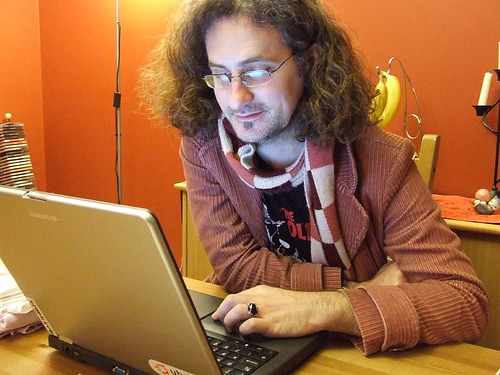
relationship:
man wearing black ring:
[159, 2, 489, 353] [248, 301, 258, 319]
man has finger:
[159, 2, 489, 353] [223, 299, 261, 335]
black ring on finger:
[248, 301, 258, 319] [223, 299, 261, 335]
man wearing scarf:
[159, 2, 489, 353] [197, 109, 385, 254]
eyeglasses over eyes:
[179, 61, 293, 95] [214, 67, 268, 83]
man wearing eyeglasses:
[159, 2, 489, 353] [179, 61, 293, 95]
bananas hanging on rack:
[374, 55, 401, 128] [373, 53, 423, 160]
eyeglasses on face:
[200, 52, 297, 90] [198, 3, 310, 145]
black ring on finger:
[248, 300, 258, 319] [223, 304, 254, 332]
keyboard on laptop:
[203, 330, 281, 374] [3, 174, 335, 374]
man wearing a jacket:
[159, 2, 489, 353] [177, 116, 489, 354]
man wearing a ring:
[159, 2, 489, 353] [245, 301, 257, 315]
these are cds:
[2, 110, 42, 180] [1, 107, 56, 222]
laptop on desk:
[3, 174, 335, 374] [0, 230, 499, 375]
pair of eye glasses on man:
[174, 116, 252, 196] [123, 3, 493, 353]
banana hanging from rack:
[386, 94, 406, 118] [373, 53, 423, 160]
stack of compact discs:
[10, 120, 40, 203] [1, 122, 36, 194]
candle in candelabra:
[477, 71, 492, 109] [467, 63, 497, 145]